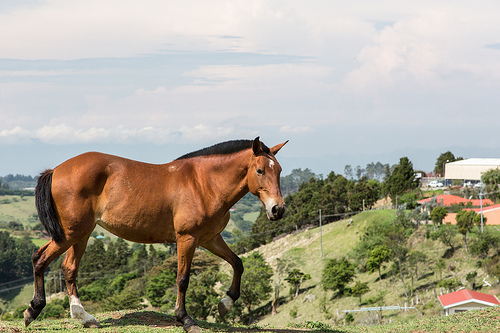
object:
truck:
[423, 177, 443, 189]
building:
[439, 153, 499, 195]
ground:
[411, 311, 486, 332]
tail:
[31, 165, 68, 251]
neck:
[210, 144, 250, 211]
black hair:
[172, 137, 277, 159]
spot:
[266, 157, 276, 172]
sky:
[343, 0, 499, 163]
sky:
[0, 0, 131, 176]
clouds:
[2, 0, 126, 59]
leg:
[173, 207, 200, 331]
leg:
[197, 233, 244, 315]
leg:
[61, 212, 96, 328]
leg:
[22, 206, 94, 326]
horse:
[20, 135, 288, 331]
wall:
[453, 305, 478, 315]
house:
[415, 193, 500, 225]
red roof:
[413, 194, 492, 210]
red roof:
[436, 287, 498, 308]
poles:
[318, 208, 323, 249]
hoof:
[217, 297, 237, 318]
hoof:
[172, 316, 201, 332]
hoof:
[65, 304, 100, 331]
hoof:
[21, 307, 37, 329]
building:
[433, 287, 499, 317]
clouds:
[209, 56, 337, 81]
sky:
[144, 0, 299, 148]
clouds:
[360, 20, 450, 81]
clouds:
[2, 123, 253, 142]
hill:
[222, 208, 499, 331]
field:
[0, 172, 499, 332]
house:
[435, 288, 499, 316]